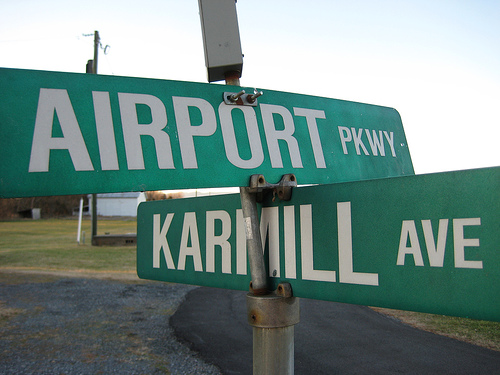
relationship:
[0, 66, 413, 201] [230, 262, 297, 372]
sign on pole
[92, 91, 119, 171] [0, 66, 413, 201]
letter on sign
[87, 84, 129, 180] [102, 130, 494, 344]
letter on sign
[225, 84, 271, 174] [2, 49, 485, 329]
letter on sign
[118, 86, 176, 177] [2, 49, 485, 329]
letter on sign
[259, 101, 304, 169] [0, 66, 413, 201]
letter on a sign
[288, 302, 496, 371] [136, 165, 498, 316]
road behind signs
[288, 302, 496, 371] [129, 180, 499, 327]
road behind sign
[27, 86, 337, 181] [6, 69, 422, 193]
lettering on background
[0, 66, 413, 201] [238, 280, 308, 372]
sign on pole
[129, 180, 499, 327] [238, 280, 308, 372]
sign on pole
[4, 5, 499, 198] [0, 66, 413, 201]
sky over sign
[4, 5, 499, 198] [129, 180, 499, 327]
sky over sign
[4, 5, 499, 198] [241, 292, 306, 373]
sky over pole